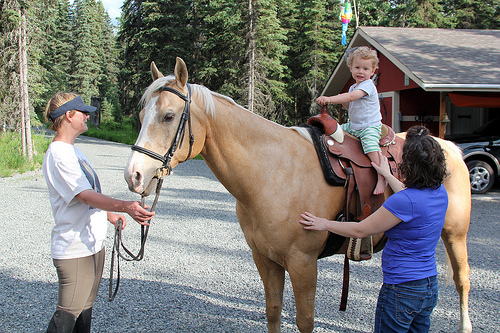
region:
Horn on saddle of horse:
[312, 97, 332, 117]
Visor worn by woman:
[48, 88, 100, 128]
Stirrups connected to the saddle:
[338, 205, 378, 266]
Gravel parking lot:
[168, 220, 231, 315]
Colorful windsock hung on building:
[329, 0, 376, 51]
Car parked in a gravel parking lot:
[447, 128, 499, 197]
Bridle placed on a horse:
[122, 63, 206, 166]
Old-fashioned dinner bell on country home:
[434, 92, 453, 127]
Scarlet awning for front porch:
[437, 86, 497, 112]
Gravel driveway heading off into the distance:
[0, 110, 125, 155]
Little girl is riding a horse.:
[85, 35, 451, 331]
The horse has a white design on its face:
[130, 58, 241, 252]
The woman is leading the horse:
[45, 89, 144, 319]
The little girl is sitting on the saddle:
[294, 26, 397, 203]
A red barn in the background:
[337, 12, 497, 89]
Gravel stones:
[165, 261, 206, 330]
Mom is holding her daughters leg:
[355, 122, 463, 331]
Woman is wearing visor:
[39, 75, 110, 152]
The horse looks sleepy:
[103, 39, 232, 225]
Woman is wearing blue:
[377, 166, 471, 331]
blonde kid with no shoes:
[321, 37, 403, 184]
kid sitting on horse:
[202, 59, 429, 216]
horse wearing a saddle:
[305, 90, 426, 235]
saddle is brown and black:
[310, 105, 430, 202]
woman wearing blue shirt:
[388, 170, 450, 292]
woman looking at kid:
[404, 122, 447, 204]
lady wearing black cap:
[56, 87, 93, 151]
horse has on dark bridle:
[132, 79, 255, 210]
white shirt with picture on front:
[46, 142, 135, 267]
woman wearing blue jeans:
[378, 274, 454, 331]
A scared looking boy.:
[323, 31, 400, 192]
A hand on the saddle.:
[315, 90, 330, 111]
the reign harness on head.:
[129, 66, 199, 178]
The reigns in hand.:
[108, 191, 159, 308]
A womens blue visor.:
[36, 85, 98, 122]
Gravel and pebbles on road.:
[138, 271, 243, 329]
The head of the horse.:
[120, 54, 210, 198]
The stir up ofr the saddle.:
[339, 217, 379, 273]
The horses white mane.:
[139, 51, 313, 132]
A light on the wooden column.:
[440, 108, 452, 125]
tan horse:
[125, 57, 476, 330]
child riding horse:
[315, 44, 388, 194]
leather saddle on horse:
[305, 100, 403, 259]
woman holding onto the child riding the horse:
[299, 125, 446, 330]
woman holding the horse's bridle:
[42, 90, 154, 332]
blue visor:
[47, 96, 96, 118]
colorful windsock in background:
[335, 0, 355, 45]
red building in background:
[317, 24, 498, 143]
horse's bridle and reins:
[107, 80, 192, 300]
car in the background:
[444, 127, 499, 192]